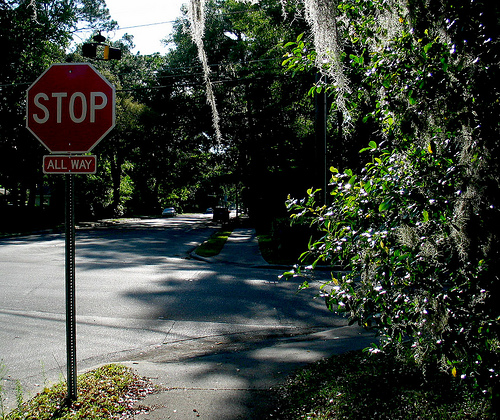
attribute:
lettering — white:
[46, 154, 71, 172]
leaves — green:
[303, 187, 320, 203]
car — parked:
[161, 204, 182, 221]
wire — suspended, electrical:
[12, 10, 220, 40]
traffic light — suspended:
[77, 30, 121, 67]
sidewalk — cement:
[154, 357, 272, 418]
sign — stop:
[15, 50, 118, 171]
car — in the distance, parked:
[157, 200, 177, 218]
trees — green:
[157, 7, 430, 261]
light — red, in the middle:
[81, 30, 124, 61]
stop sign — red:
[22, 60, 117, 179]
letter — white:
[23, 86, 108, 121]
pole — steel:
[59, 169, 80, 401]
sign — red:
[17, 64, 109, 174]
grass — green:
[14, 376, 141, 416]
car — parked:
[152, 202, 180, 219]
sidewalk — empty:
[227, 212, 267, 265]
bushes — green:
[278, 6, 484, 416]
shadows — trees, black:
[133, 272, 349, 355]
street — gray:
[21, 256, 303, 329]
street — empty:
[10, 265, 347, 330]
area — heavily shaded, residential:
[2, 60, 474, 417]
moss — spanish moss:
[299, 4, 428, 134]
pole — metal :
[58, 184, 82, 398]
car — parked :
[155, 203, 179, 218]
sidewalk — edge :
[22, 323, 347, 415]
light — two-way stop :
[99, 36, 129, 66]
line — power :
[25, 5, 326, 43]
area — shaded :
[196, 327, 326, 377]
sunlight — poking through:
[135, 261, 272, 294]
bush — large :
[293, 40, 483, 398]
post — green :
[53, 178, 80, 403]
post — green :
[57, 176, 80, 408]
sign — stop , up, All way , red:
[21, 57, 121, 179]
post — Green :
[60, 178, 81, 395]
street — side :
[4, 208, 352, 378]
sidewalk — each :
[86, 214, 338, 414]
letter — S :
[27, 89, 57, 130]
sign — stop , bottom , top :
[20, 51, 123, 175]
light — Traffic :
[26, 14, 199, 66]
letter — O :
[64, 89, 91, 135]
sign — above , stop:
[22, 58, 121, 408]